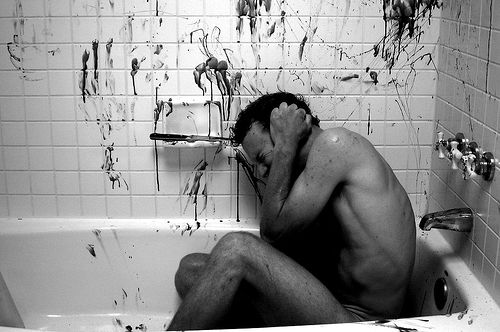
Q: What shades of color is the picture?
A: Black and white.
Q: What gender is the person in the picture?
A: Male.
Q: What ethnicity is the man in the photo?
A: Caucasian.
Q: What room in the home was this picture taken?
A: Bathroom.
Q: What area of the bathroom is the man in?
A: Bathtub.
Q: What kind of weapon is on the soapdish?
A: Knife.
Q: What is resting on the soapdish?
A: Knife.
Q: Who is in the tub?
A: Man clutching head.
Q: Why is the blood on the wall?
A: Knife wound.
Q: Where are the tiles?
A: Wall surrounding the tub.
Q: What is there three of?
A: Knobs.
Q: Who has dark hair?
A: Man in tub.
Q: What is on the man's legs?
A: Hair.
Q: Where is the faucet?
A: Behind man.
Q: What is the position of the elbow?
A: Bent.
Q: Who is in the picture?
A: A man.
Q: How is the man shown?
A: Naked.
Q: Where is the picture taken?
A: Bathroom.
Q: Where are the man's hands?
A: Over his ears.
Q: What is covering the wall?
A: Tile.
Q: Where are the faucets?
A: Back wall.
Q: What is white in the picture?
A: Tub and walls.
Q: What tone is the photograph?
A: Black and white.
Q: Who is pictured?
A: A man.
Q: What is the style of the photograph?
A: Black and white.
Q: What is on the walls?
A: Pretend blood.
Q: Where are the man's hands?
A: On his ears.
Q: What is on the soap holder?
A: A knife.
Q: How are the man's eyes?
A: Closed.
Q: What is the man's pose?
A: Sitting.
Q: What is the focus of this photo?
A: Blood streak shower with cowering man.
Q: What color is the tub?
A: White.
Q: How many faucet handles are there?
A: 3.